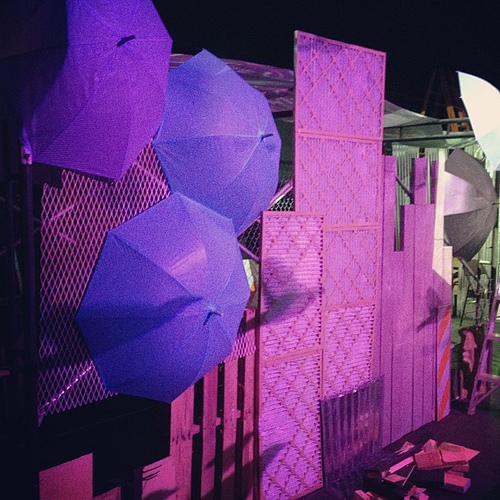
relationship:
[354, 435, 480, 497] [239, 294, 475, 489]
blocks on ground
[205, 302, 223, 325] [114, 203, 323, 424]
rod sticking out of top umbrella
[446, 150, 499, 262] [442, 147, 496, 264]
umbrella by a grey umbrella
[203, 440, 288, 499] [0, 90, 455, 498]
shadows on wall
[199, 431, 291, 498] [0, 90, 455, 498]
shadow on wall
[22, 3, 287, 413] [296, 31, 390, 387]
umbrellas hanging on wall